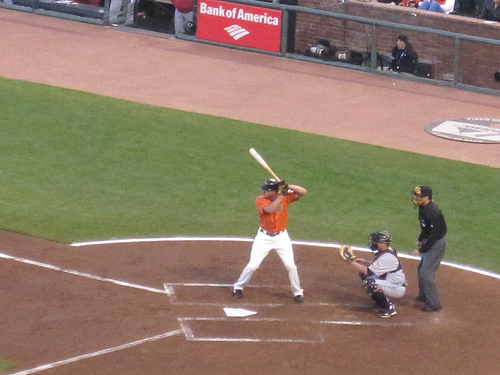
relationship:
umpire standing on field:
[411, 183, 449, 313] [0, 4, 498, 373]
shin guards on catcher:
[367, 285, 394, 315] [338, 228, 408, 321]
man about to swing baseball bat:
[205, 151, 326, 304] [242, 146, 293, 196]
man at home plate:
[205, 151, 326, 304] [213, 286, 265, 328]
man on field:
[230, 175, 307, 306] [0, 4, 498, 373]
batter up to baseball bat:
[232, 175, 313, 299] [242, 146, 293, 196]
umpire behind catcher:
[404, 183, 446, 315] [407, 182, 445, 308]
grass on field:
[9, 73, 495, 315] [4, 85, 467, 373]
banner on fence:
[195, 0, 283, 55] [1, 0, 498, 97]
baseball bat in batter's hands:
[242, 146, 293, 196] [277, 176, 290, 195]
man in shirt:
[410, 173, 457, 325] [409, 203, 455, 257]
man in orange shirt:
[225, 167, 308, 302] [250, 190, 305, 232]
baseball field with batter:
[2, 83, 498, 373] [229, 173, 314, 305]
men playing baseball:
[212, 132, 459, 331] [125, 41, 490, 364]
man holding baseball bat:
[225, 140, 322, 306] [247, 141, 287, 184]